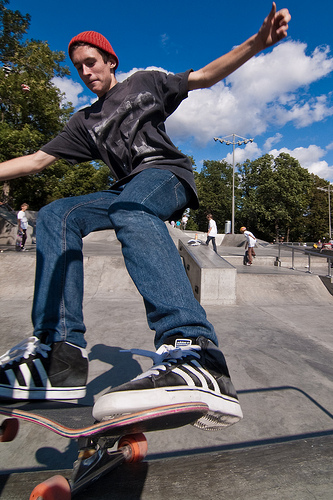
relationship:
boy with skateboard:
[0, 2, 291, 431] [0, 395, 208, 499]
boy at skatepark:
[0, 2, 291, 432] [0, 218, 331, 497]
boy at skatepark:
[237, 223, 259, 269] [0, 218, 331, 497]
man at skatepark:
[202, 212, 219, 251] [0, 218, 331, 497]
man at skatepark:
[16, 199, 29, 253] [0, 218, 331, 497]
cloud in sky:
[165, 40, 332, 143] [1, 0, 332, 186]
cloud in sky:
[260, 132, 282, 150] [1, 0, 332, 186]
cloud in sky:
[264, 144, 332, 181] [1, 0, 332, 186]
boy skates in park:
[0, 2, 291, 431] [0, 218, 331, 498]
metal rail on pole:
[279, 239, 330, 261] [289, 245, 298, 268]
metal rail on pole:
[279, 239, 330, 261] [324, 257, 332, 281]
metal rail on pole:
[279, 239, 330, 261] [304, 254, 314, 274]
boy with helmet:
[230, 223, 267, 278] [231, 222, 249, 231]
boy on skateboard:
[0, 2, 291, 432] [0, 382, 210, 498]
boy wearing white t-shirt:
[0, 2, 291, 432] [203, 218, 221, 238]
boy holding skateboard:
[0, 2, 291, 432] [9, 356, 240, 446]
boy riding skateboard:
[0, 2, 291, 432] [0, 395, 208, 499]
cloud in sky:
[165, 40, 332, 143] [1, 2, 331, 236]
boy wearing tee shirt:
[0, 2, 291, 432] [37, 68, 200, 211]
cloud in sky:
[165, 40, 332, 143] [2, 3, 331, 205]